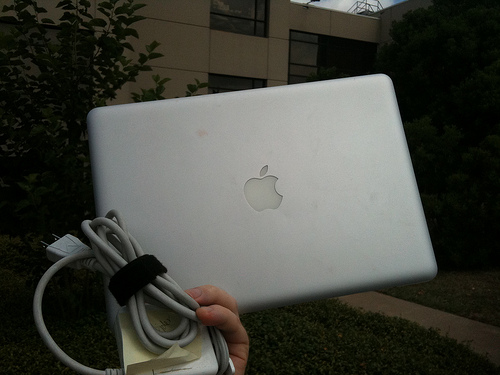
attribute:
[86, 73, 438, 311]
laptop — white, gray, metal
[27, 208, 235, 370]
plug — white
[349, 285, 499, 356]
sidewalk — concrete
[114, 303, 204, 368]
post it — yellow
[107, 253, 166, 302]
strap — black, velcro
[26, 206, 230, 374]
cord — gray, wrapped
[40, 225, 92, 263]
plug — gray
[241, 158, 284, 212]
apple — bitten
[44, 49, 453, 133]
building — tan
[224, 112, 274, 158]
windows — dark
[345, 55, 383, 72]
structure — airy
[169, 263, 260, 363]
fingers — curved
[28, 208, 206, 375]
wires — bundled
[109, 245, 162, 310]
strap — black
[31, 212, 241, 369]
cord — curved, gray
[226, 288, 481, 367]
grass — growing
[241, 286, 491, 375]
grass — wild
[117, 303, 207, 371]
note — sticky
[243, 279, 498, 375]
bush — green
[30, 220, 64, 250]
prongs — metal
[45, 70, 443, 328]
computer — white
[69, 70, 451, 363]
laptop — silver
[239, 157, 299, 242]
logo — silver, tiny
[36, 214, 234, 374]
cords — silver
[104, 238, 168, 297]
strap — black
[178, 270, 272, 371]
fingers — wrapped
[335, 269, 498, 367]
sidewalk — concrete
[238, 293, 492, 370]
grass patch — dark green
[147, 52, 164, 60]
leaf — green